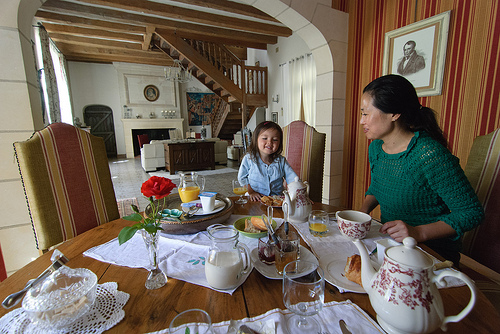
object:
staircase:
[182, 46, 270, 129]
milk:
[203, 259, 241, 287]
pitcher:
[203, 224, 253, 290]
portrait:
[377, 17, 443, 99]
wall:
[340, 18, 380, 150]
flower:
[126, 177, 174, 231]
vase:
[143, 229, 168, 291]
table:
[0, 196, 493, 327]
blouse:
[362, 136, 483, 248]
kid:
[236, 120, 298, 197]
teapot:
[279, 180, 312, 225]